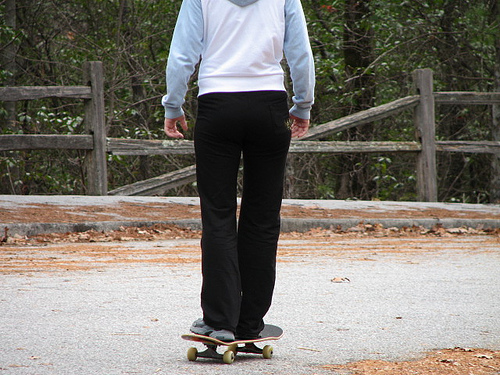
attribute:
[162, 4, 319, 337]
person — skateboarding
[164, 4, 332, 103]
shirt — blue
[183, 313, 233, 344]
shoe — gray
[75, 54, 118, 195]
post — wood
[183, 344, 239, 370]
wheels — white, yellow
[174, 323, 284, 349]
skateboard — black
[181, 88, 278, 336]
pants — black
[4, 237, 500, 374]
road — paved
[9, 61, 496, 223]
fence — picket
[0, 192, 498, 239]
pavement — gray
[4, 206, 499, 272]
ground — orange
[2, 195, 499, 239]
sidewalk — gray